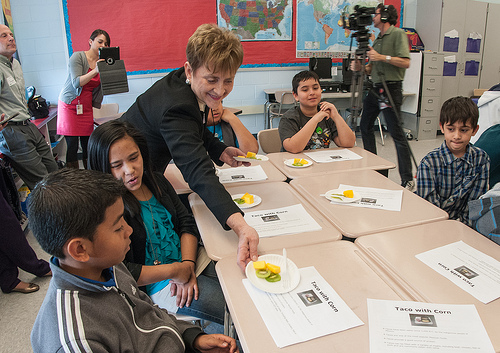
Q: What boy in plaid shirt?
A: Boy left side of table.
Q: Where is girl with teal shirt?
A: Beside boy on left.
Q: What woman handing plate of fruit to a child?
A: Woman in black jacket.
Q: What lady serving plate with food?
A: Lady with two plates.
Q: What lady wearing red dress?
A: Lady with blue sweater.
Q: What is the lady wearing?
A: A jacket.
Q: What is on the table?
A: Papers.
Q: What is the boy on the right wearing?
A: Blue and gray plaid shirt.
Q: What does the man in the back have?
A: Camera.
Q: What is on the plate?
A: Fruit.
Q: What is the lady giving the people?
A: Meal.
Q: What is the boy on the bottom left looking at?
A: Plate.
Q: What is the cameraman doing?
A: Filming.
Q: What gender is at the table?
A: Male and female.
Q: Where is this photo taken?
A: Classroom.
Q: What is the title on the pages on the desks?
A: "Taco with Corn".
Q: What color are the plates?
A: White.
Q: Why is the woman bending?
A: To place the plate down.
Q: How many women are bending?
A: One.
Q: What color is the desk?
A: Tan.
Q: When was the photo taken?
A: Day time.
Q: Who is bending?
A: The woman.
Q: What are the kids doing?
A: Sitting.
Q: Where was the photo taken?
A: In a classroom.